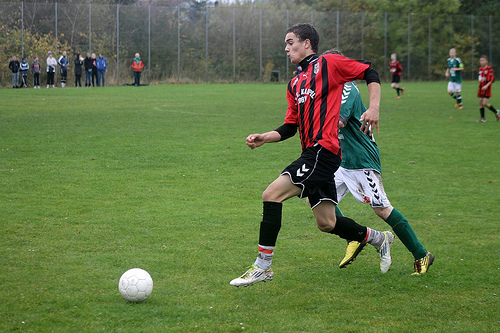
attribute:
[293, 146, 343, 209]
shorts — black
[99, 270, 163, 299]
ball — white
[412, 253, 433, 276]
shoes — yellow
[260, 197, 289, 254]
socks — black, tall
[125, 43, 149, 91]
jackst — red, green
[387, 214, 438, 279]
socks — green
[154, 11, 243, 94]
fence — high, metal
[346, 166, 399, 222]
shorts — white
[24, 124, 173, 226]
grass — green, lush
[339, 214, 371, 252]
sock — long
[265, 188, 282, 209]
knee — bent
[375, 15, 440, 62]
leaves — green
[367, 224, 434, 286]
cleats — yellow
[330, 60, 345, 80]
shirt — red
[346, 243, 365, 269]
cleat — yellow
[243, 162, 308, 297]
leg — uncovered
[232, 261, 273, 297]
shoes — white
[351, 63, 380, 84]
sleeve — black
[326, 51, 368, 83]
sleeve — short